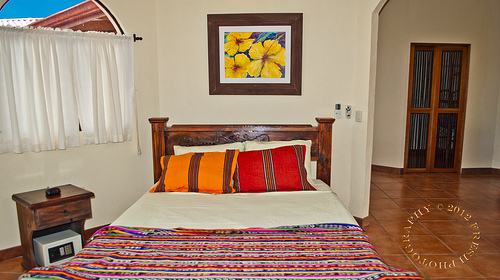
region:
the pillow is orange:
[171, 159, 185, 181]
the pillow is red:
[277, 156, 290, 172]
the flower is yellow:
[256, 50, 275, 68]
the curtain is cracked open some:
[53, 61, 100, 143]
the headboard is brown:
[176, 125, 200, 142]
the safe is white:
[44, 234, 76, 259]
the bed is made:
[221, 192, 263, 228]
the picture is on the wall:
[203, 8, 245, 31]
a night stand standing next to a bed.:
[12, 180, 143, 279]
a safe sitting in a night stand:
[25, 237, 110, 265]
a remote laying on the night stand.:
[16, 174, 89, 212]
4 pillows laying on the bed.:
[128, 98, 363, 195]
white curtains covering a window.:
[1, 17, 151, 152]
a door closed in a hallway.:
[403, 44, 484, 208]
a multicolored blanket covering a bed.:
[125, 215, 234, 278]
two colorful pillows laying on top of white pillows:
[162, 156, 316, 203]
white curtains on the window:
[2, 32, 138, 142]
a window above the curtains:
[6, 1, 127, 34]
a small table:
[23, 191, 88, 259]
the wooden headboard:
[148, 118, 333, 173]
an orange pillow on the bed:
[153, 155, 231, 188]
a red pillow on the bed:
[234, 148, 310, 190]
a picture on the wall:
[204, 15, 299, 91]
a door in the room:
[410, 33, 464, 173]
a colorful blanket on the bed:
[86, 223, 363, 274]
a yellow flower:
[250, 38, 287, 73]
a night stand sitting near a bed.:
[19, 169, 159, 266]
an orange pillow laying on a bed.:
[146, 143, 236, 210]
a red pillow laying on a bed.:
[238, 150, 363, 218]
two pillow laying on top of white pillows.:
[170, 138, 316, 227]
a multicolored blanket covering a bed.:
[82, 225, 377, 266]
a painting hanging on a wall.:
[201, 16, 328, 110]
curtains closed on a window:
[10, 31, 138, 151]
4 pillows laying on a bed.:
[136, 128, 339, 221]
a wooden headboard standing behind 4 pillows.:
[151, 114, 345, 165]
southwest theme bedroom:
[1, 3, 485, 275]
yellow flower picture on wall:
[200, 9, 309, 102]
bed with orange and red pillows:
[130, 113, 341, 275]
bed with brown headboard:
[141, 110, 345, 279]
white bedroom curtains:
[0, 23, 150, 158]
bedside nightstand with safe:
[3, 178, 98, 269]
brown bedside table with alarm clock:
[8, 180, 95, 270]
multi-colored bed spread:
[138, 110, 363, 278]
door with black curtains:
[397, 35, 477, 180]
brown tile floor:
[375, 169, 499, 239]